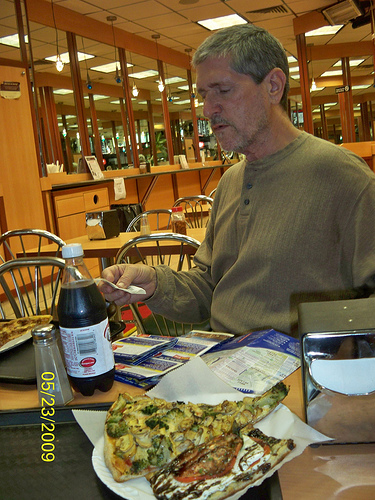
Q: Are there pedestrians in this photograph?
A: No, there are no pedestrians.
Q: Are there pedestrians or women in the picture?
A: No, there are no pedestrians or women.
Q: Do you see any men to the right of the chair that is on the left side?
A: Yes, there is a man to the right of the chair.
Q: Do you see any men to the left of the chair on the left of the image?
A: No, the man is to the right of the chair.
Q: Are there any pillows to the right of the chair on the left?
A: No, there is a man to the right of the chair.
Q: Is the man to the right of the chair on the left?
A: Yes, the man is to the right of the chair.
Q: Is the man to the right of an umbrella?
A: No, the man is to the right of the chair.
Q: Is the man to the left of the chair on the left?
A: No, the man is to the right of the chair.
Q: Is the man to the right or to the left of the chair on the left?
A: The man is to the right of the chair.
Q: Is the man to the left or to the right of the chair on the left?
A: The man is to the right of the chair.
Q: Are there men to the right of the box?
A: Yes, there is a man to the right of the box.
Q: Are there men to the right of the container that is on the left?
A: Yes, there is a man to the right of the box.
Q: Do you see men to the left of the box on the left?
A: No, the man is to the right of the box.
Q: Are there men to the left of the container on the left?
A: No, the man is to the right of the box.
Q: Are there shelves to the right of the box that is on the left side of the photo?
A: No, there is a man to the right of the box.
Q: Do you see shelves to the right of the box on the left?
A: No, there is a man to the right of the box.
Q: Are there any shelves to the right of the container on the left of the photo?
A: No, there is a man to the right of the box.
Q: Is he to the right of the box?
A: Yes, the man is to the right of the box.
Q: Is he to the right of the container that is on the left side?
A: Yes, the man is to the right of the box.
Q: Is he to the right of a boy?
A: No, the man is to the right of the box.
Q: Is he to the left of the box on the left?
A: No, the man is to the right of the box.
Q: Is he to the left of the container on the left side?
A: No, the man is to the right of the box.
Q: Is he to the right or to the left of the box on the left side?
A: The man is to the right of the box.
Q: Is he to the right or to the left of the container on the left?
A: The man is to the right of the box.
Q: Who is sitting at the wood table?
A: The man is sitting at the table.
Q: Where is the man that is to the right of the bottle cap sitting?
A: The man is sitting at the table.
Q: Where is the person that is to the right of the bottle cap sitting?
A: The man is sitting at the table.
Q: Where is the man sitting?
A: The man is sitting at the table.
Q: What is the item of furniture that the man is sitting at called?
A: The piece of furniture is a table.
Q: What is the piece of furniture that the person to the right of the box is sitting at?
A: The piece of furniture is a table.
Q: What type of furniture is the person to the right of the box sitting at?
A: The man is sitting at the table.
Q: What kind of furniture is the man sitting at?
A: The man is sitting at the table.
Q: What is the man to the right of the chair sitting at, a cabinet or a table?
A: The man is sitting at a table.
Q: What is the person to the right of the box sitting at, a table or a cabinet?
A: The man is sitting at a table.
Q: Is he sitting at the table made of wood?
A: Yes, the man is sitting at the table.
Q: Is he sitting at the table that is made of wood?
A: Yes, the man is sitting at the table.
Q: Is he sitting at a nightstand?
A: No, the man is sitting at the table.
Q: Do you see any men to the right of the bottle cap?
A: Yes, there is a man to the right of the bottle cap.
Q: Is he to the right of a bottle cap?
A: Yes, the man is to the right of a bottle cap.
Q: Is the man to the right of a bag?
A: No, the man is to the right of a bottle cap.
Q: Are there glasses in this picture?
A: No, there are no glasses.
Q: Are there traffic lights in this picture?
A: No, there are no traffic lights.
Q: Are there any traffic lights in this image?
A: No, there are no traffic lights.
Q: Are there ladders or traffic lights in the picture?
A: No, there are no traffic lights or ladders.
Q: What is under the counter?
A: The garbage can is under the counter.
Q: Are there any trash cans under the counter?
A: Yes, there is a trash can under the counter.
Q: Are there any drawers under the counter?
A: No, there is a trash can under the counter.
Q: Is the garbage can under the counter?
A: Yes, the garbage can is under the counter.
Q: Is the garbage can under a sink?
A: No, the garbage can is under the counter.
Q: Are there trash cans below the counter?
A: Yes, there is a trash can below the counter.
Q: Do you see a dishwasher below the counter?
A: No, there is a trash can below the counter.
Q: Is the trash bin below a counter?
A: Yes, the trash bin is below a counter.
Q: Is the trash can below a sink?
A: No, the trash can is below a counter.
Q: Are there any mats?
A: No, there are no mats.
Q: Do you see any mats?
A: No, there are no mats.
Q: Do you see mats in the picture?
A: No, there are no mats.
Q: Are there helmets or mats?
A: No, there are no mats or helmets.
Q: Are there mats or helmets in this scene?
A: No, there are no mats or helmets.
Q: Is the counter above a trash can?
A: Yes, the counter is above a trash can.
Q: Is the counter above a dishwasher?
A: No, the counter is above a trash can.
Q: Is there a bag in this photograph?
A: No, there are no bags.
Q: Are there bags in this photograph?
A: No, there are no bags.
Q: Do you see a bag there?
A: No, there are no bags.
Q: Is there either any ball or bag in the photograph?
A: No, there are no bags or balls.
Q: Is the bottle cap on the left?
A: Yes, the bottle cap is on the left of the image.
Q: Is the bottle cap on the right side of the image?
A: No, the bottle cap is on the left of the image.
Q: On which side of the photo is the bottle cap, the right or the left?
A: The bottle cap is on the left of the image.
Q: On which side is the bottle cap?
A: The bottle cap is on the left of the image.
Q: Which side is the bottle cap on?
A: The bottle cap is on the left of the image.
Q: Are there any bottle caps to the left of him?
A: Yes, there is a bottle cap to the left of the man.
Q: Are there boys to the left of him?
A: No, there is a bottle cap to the left of the man.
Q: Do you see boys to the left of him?
A: No, there is a bottle cap to the left of the man.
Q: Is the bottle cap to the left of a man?
A: Yes, the bottle cap is to the left of a man.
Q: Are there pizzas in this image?
A: Yes, there is a pizza.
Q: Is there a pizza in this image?
A: Yes, there is a pizza.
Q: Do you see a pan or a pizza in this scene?
A: Yes, there is a pizza.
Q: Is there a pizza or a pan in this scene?
A: Yes, there is a pizza.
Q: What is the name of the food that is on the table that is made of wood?
A: The food is a pizza.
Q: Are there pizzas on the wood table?
A: Yes, there is a pizza on the table.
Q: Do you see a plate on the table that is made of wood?
A: No, there is a pizza on the table.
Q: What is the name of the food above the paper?
A: The food is a pizza.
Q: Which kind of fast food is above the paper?
A: The food is a pizza.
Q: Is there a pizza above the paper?
A: Yes, there is a pizza above the paper.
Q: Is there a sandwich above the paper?
A: No, there is a pizza above the paper.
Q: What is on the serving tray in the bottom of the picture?
A: The pizza is on the food tray.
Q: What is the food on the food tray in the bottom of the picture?
A: The food is a pizza.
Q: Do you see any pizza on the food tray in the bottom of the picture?
A: Yes, there is a pizza on the food tray.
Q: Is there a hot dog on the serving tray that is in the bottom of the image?
A: No, there is a pizza on the serving tray.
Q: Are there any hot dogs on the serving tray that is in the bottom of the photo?
A: No, there is a pizza on the serving tray.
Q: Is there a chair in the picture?
A: Yes, there is a chair.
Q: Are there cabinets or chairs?
A: Yes, there is a chair.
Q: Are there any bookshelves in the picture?
A: No, there are no bookshelves.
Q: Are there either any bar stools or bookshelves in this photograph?
A: No, there are no bookshelves or bar stools.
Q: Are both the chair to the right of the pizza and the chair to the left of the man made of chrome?
A: Yes, both the chair and the chair are made of chrome.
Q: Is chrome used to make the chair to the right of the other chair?
A: Yes, the chair is made of chrome.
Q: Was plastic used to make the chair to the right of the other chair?
A: No, the chair is made of chrome.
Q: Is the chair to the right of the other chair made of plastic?
A: No, the chair is made of chrome.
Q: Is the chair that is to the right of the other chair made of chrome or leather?
A: The chair is made of chrome.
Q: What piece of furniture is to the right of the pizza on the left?
A: The piece of furniture is a chair.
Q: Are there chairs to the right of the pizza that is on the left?
A: Yes, there is a chair to the right of the pizza.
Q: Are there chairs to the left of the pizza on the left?
A: No, the chair is to the right of the pizza.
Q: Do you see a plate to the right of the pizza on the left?
A: No, there is a chair to the right of the pizza.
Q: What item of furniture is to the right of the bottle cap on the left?
A: The piece of furniture is a chair.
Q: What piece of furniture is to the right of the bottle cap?
A: The piece of furniture is a chair.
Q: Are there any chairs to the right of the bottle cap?
A: Yes, there is a chair to the right of the bottle cap.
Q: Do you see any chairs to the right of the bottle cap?
A: Yes, there is a chair to the right of the bottle cap.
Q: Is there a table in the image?
A: Yes, there is a table.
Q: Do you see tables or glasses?
A: Yes, there is a table.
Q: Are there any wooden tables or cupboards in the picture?
A: Yes, there is a wood table.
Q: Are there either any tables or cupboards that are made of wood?
A: Yes, the table is made of wood.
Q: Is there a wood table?
A: Yes, there is a wood table.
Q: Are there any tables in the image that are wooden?
A: Yes, there is a table that is wooden.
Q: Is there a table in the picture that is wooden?
A: Yes, there is a table that is wooden.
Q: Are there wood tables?
A: Yes, there is a table that is made of wood.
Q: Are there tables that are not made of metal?
A: Yes, there is a table that is made of wood.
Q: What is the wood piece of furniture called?
A: The piece of furniture is a table.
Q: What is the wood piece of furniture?
A: The piece of furniture is a table.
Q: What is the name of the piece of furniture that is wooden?
A: The piece of furniture is a table.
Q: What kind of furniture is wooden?
A: The furniture is a table.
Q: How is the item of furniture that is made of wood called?
A: The piece of furniture is a table.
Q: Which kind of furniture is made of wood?
A: The furniture is a table.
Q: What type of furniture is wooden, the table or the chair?
A: The table is wooden.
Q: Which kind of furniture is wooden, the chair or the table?
A: The table is wooden.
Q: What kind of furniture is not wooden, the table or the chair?
A: The chair is not wooden.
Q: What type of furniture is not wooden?
A: The furniture is a chair.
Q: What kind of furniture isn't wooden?
A: The furniture is a chair.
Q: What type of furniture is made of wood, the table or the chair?
A: The table is made of wood.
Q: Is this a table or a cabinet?
A: This is a table.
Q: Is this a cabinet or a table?
A: This is a table.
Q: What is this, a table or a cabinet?
A: This is a table.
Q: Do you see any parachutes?
A: No, there are no parachutes.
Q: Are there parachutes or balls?
A: No, there are no parachutes or balls.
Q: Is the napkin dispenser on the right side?
A: Yes, the napkin dispenser is on the right of the image.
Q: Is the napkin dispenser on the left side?
A: No, the napkin dispenser is on the right of the image.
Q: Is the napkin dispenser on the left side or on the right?
A: The napkin dispenser is on the right of the image.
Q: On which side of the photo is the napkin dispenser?
A: The napkin dispenser is on the right of the image.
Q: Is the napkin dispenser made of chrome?
A: Yes, the napkin dispenser is made of chrome.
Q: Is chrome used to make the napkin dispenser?
A: Yes, the napkin dispenser is made of chrome.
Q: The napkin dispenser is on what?
A: The napkin dispenser is on the table.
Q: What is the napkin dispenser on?
A: The napkin dispenser is on the table.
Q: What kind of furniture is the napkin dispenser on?
A: The napkin dispenser is on the table.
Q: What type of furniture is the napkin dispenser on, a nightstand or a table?
A: The napkin dispenser is on a table.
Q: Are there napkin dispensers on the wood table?
A: Yes, there is a napkin dispenser on the table.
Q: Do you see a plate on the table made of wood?
A: No, there is a napkin dispenser on the table.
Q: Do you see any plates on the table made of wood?
A: No, there is a napkin dispenser on the table.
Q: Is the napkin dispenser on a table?
A: Yes, the napkin dispenser is on a table.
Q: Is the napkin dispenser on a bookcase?
A: No, the napkin dispenser is on a table.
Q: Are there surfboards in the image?
A: No, there are no surfboards.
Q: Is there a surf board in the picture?
A: No, there are no surfboards.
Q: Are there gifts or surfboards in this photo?
A: No, there are no surfboards or gifts.